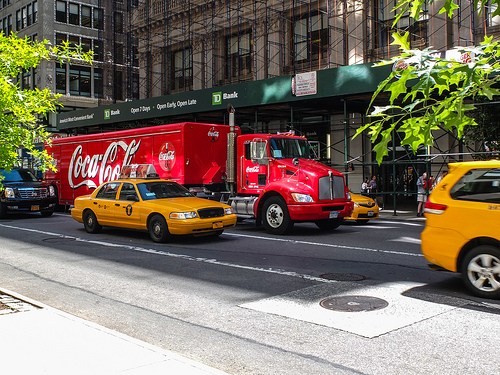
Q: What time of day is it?
A: Morning.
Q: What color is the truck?
A: Red.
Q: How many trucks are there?
A: One.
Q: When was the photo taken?
A: Day time.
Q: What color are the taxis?
A: Yellow.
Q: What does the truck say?
A: Coca Cola.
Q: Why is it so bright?
A: Sunny.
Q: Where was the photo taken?
A: Next to a street.